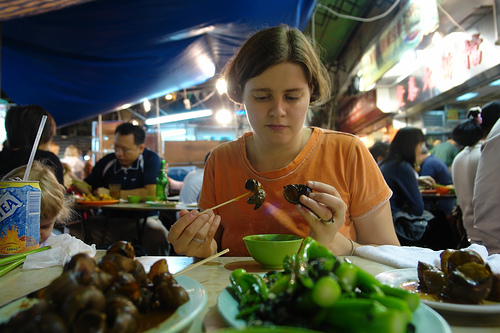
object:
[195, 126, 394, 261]
shirt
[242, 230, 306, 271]
bowl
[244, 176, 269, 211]
meat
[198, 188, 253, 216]
stick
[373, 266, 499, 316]
plate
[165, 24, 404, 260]
woman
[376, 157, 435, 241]
shirt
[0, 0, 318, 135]
tarp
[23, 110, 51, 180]
straw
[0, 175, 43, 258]
can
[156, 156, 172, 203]
bottle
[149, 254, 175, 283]
snail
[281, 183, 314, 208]
shell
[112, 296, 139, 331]
escargot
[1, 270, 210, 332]
dish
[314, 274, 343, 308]
vegetable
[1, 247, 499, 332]
table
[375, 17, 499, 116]
sign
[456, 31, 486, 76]
asian language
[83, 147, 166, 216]
shirt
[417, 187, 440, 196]
tray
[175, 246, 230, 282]
stick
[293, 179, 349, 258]
left hand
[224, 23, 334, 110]
hair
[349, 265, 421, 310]
asparagus spear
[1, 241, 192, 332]
pile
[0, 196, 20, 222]
tea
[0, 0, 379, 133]
ceiling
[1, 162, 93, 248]
child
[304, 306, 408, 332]
vegetable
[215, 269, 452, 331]
plate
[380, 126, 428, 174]
hair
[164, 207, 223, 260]
hand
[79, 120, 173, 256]
man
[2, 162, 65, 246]
head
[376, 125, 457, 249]
person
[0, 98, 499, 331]
eating area